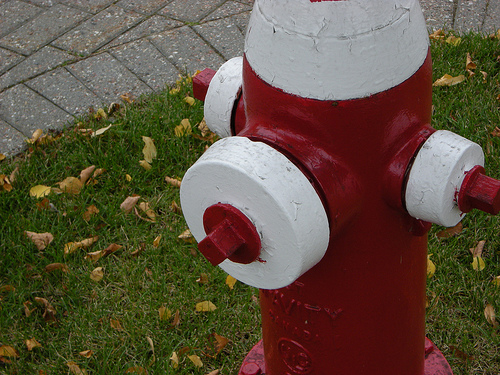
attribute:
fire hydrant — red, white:
[178, 1, 499, 374]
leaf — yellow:
[29, 184, 51, 200]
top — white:
[244, 0, 429, 100]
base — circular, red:
[241, 333, 454, 374]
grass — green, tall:
[2, 34, 497, 374]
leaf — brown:
[30, 231, 54, 254]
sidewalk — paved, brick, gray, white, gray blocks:
[0, 0, 500, 157]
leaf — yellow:
[433, 73, 468, 87]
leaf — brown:
[120, 197, 138, 216]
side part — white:
[398, 130, 499, 227]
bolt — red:
[200, 205, 262, 266]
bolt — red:
[192, 65, 217, 103]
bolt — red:
[458, 166, 499, 216]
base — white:
[407, 130, 485, 230]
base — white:
[204, 57, 244, 136]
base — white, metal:
[177, 133, 328, 289]